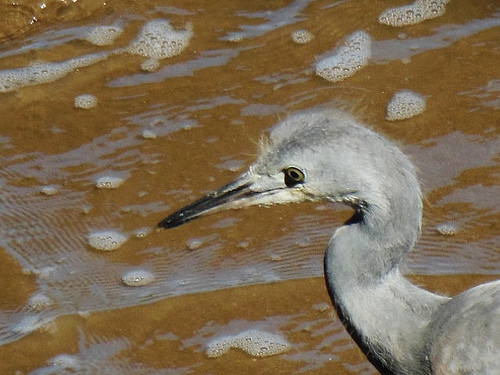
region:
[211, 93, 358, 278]
the bird has eye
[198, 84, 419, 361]
the bird has eye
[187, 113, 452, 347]
bird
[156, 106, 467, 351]
gray bird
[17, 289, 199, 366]
white ocean foam on brown beach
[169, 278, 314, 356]
white ocean foam on brown beach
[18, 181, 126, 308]
white ocean foam on brown beach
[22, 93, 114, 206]
white ocean foam on brown beach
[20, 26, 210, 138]
white ocean foam on brown beach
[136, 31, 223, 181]
white ocean foam on brown beach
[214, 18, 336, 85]
white ocean foam on brown beach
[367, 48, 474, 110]
white ocean foam on brown beach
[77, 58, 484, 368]
grey bird in front of shallow water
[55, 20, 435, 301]
white bubbles floating on surface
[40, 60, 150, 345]
deep brown sand under clear water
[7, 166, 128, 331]
white lines and grids in water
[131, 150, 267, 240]
long black beak with grey stripes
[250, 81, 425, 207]
fuzzy light feathers on head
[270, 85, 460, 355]
neck in series of curves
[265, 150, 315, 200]
black and yellow eye looking down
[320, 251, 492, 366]
feathers laying close to body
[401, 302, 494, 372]
lighter gray circular markings on body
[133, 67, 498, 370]
long necked white bird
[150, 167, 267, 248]
black heron's beak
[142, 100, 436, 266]
head of gray and white water bird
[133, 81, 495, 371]
gray and white water fowl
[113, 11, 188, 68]
bubbles in surface of water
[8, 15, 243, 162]
shallow water with dirt river bed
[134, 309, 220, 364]
dirt river bed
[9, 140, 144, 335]
cloudy stripe pattern in water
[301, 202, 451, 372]
neck of white and gray bird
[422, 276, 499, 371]
gray and white heron feathers